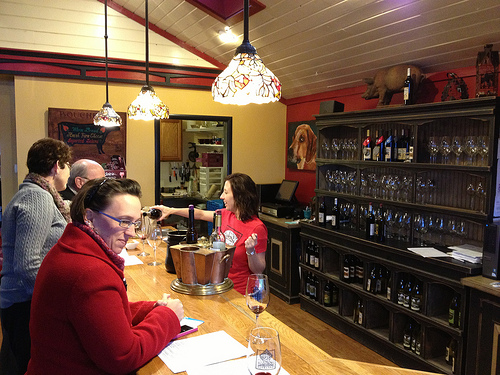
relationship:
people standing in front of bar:
[28, 174, 184, 374] [5, 212, 487, 374]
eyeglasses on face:
[85, 205, 140, 228] [92, 192, 140, 255]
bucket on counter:
[165, 242, 237, 296] [121, 238, 438, 371]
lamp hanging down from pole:
[91, 0, 282, 129] [240, 3, 252, 52]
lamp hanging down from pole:
[91, 0, 282, 129] [141, 1, 155, 90]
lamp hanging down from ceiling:
[91, 0, 282, 129] [2, 5, 496, 75]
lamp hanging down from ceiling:
[207, 8, 287, 115] [2, 5, 496, 75]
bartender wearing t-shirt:
[148, 174, 267, 297] [216, 213, 266, 296]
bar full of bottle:
[1, 3, 482, 365] [403, 67, 415, 103]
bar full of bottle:
[1, 3, 482, 365] [365, 128, 372, 158]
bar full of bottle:
[1, 3, 482, 365] [374, 130, 384, 161]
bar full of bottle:
[1, 3, 482, 365] [387, 130, 394, 159]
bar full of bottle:
[1, 3, 482, 365] [399, 128, 409, 158]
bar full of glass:
[1, 3, 482, 365] [323, 140, 330, 159]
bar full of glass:
[1, 3, 482, 365] [331, 143, 338, 159]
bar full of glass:
[1, 3, 482, 365] [329, 172, 336, 186]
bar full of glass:
[1, 3, 482, 365] [246, 268, 270, 328]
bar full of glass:
[1, 3, 482, 365] [249, 329, 282, 372]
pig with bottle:
[356, 62, 431, 105] [398, 62, 416, 104]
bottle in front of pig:
[398, 62, 416, 104] [356, 62, 431, 105]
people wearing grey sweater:
[0, 137, 74, 375] [0, 179, 69, 309]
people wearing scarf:
[0, 137, 74, 375] [23, 174, 71, 223]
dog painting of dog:
[288, 124, 317, 171] [294, 126, 315, 169]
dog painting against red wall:
[288, 124, 317, 171] [283, 95, 322, 198]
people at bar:
[48, 157, 113, 225] [63, 214, 440, 374]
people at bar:
[1, 137, 80, 373] [63, 214, 440, 374]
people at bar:
[26, 174, 184, 374] [63, 214, 440, 374]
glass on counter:
[247, 327, 281, 374] [102, 247, 328, 374]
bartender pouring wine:
[146, 172, 268, 300] [139, 204, 163, 218]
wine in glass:
[139, 204, 163, 218] [144, 224, 166, 267]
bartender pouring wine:
[146, 172, 268, 300] [143, 208, 163, 218]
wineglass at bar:
[138, 210, 155, 241] [1, 3, 482, 365]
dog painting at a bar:
[285, 120, 318, 172] [64, 183, 416, 372]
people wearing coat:
[28, 174, 184, 374] [15, 224, 178, 371]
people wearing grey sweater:
[0, 137, 74, 375] [3, 179, 73, 306]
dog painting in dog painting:
[288, 124, 317, 171] [288, 124, 317, 171]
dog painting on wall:
[288, 124, 317, 171] [289, 60, 499, 201]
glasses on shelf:
[419, 134, 496, 164] [297, 96, 500, 375]